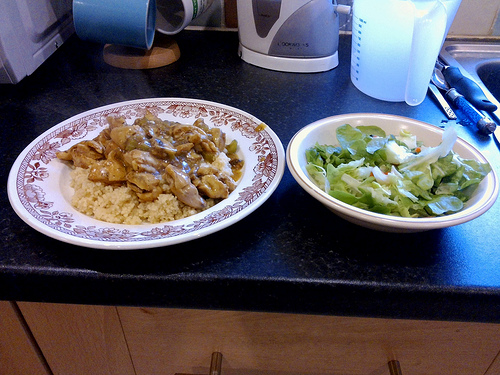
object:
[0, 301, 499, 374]
cabinets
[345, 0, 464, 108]
cup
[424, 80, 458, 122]
utensil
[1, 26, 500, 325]
counter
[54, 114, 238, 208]
meat stew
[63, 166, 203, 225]
rice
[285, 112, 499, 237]
white bowl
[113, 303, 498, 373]
drawer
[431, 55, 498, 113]
utensils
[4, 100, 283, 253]
plate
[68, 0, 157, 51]
cup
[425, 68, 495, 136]
spoon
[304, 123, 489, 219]
salad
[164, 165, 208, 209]
meat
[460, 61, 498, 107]
sink